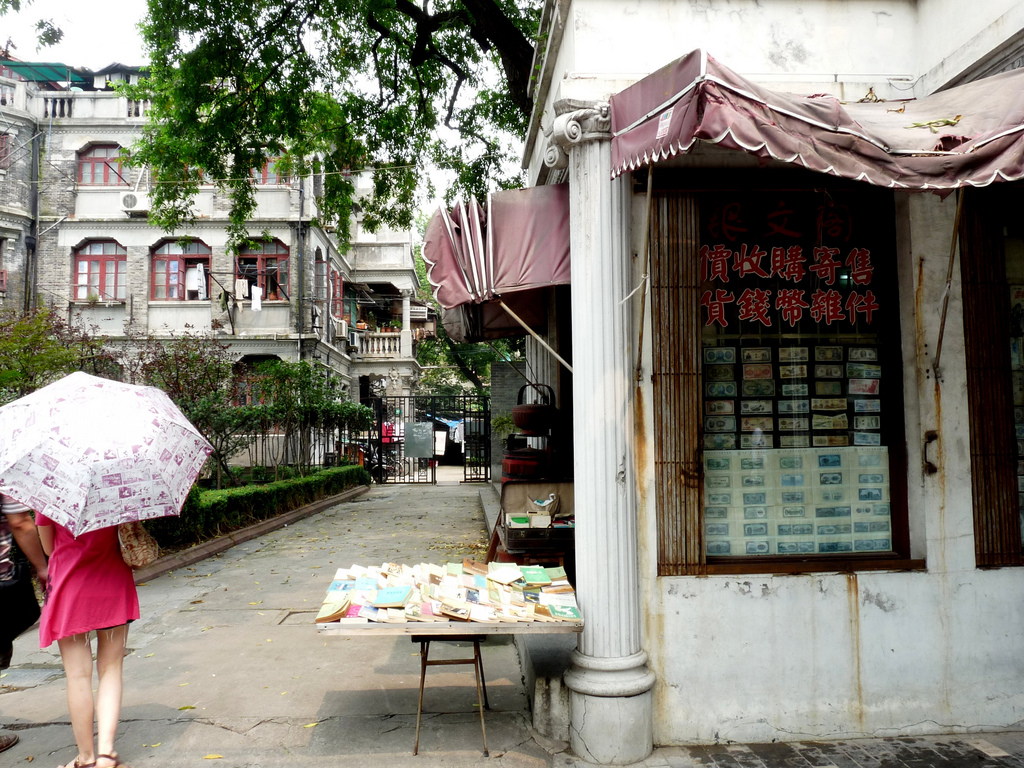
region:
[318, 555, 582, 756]
display table outside a city store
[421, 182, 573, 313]
awning over an entrance to a store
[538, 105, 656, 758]
decorative pillar on corner of building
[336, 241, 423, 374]
balcony on the side of a building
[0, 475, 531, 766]
gray slate sidewalk next to trimmed green hedge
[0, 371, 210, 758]
woman with pink dress and umbrella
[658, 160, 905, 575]
display window of a store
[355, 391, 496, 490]
black iron gate into an alleyway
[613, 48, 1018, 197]
awning over windows on a store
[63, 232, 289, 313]
three windows in the side of a building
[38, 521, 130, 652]
the woman wears a dress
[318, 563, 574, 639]
the table has many books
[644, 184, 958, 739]
the wall has rust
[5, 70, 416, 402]
the building has windows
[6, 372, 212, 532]
the umbrella has a pattern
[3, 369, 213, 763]
the girl is walking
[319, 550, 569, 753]
the table is large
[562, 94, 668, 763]
the column is long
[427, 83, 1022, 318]
the awning is wine colored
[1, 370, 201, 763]
girl holding umbrella in walkway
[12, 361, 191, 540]
white and pink umbrella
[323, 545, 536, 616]
white papers on table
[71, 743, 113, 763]
pink sandals on woman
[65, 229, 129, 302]
red window frames on building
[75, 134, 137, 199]
red window frames on building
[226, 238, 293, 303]
red window frames on building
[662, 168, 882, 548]
rows of pictures in window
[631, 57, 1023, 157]
red awning on window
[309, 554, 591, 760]
makeshift table covered with books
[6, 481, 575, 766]
cracked concrete walkway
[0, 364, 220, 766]
woman carrying a sun umbrella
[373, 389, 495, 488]
wrought iron gate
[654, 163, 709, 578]
bamboo window shade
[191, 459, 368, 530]
row of trimmed hedges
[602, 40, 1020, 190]
sagging purple window awning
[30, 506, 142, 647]
short cherry colored dress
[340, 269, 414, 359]
enclosed second floor balcony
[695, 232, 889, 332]
sign with Oriental writing on it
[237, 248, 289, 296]
A window on a building.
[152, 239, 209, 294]
A window on a building.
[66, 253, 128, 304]
A window on a building.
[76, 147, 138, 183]
A window on a building.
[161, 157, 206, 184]
A window on a building.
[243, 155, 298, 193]
A window on a building.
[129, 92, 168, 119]
A window on a building.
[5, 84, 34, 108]
A window on a building.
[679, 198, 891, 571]
A window on a building.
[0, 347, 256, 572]
top of the umbrella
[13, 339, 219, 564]
design on the umbrella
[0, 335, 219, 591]
light umbrella over the person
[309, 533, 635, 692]
table next to lady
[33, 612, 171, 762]
legs of the person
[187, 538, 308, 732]
ground next to lady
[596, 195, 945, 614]
window near the lady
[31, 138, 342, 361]
windows on the building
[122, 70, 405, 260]
leaves above the ground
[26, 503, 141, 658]
bright pink sundress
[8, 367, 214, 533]
open white and pink umbrella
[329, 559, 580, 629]
books on table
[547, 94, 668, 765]
white stone column